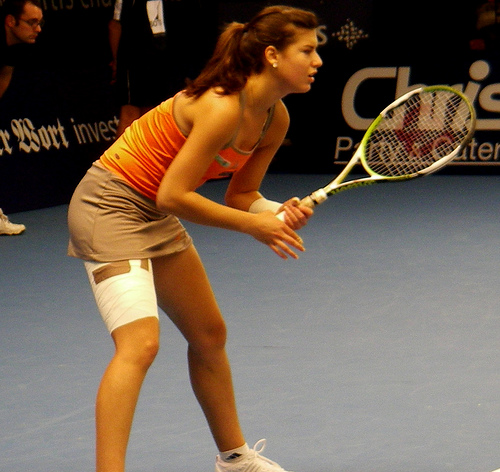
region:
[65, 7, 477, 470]
tennis player ready to receive serve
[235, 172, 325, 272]
a two hand grip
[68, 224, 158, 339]
a thigh wrapped because of injury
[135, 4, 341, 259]
woman with a nice tan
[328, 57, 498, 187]
sign written in English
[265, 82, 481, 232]
a white and green racquet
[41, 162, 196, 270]
a tan tennis skirt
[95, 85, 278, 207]
female player with orange top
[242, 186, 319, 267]
player flexing her right hand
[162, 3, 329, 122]
tennis player with a pony tail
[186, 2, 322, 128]
the girl has brown hair in a ponytail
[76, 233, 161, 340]
the girl has an ace bandage on her thigh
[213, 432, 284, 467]
she is wearing white tennis shoes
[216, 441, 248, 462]
she is wearing a white sock with a black logo on it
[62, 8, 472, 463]
the tennis player is waiting for a serve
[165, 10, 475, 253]
a tennis racket is in both hands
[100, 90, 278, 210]
an orange and gray shirt is on the girl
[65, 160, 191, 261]
the player is wearing a beige tennis skirt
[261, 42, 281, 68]
an earring is on her earlobe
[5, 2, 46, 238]
a lineman is wearing glasses on the side line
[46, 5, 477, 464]
a girl is playing tennis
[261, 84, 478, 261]
the girl has a tennis racket in both hands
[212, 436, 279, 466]
the player is wearing white tennis shoes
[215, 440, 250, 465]
the player is wearing socks with a logo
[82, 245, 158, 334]
an ace bandage is on the girl's thigh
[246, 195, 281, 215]
the girl is wearing a wrist band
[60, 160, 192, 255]
player is wearing a beige skirt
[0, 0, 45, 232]
a man is crouching behind her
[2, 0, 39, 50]
the man in a dark shirt is wearing glasses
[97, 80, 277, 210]
the tennis player is wearing a tank top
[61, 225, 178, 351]
a white leg bandage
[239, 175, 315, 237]
a taped up wrist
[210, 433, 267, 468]
a white adidas sock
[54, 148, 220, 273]
a short khaki skirt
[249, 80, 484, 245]
green and white tennis racket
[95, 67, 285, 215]
orange and tan athletic shirt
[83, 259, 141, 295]
brown tape on white bandage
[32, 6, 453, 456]
a woman playing tennis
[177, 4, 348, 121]
a woman with a brown ponytail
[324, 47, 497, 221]
a black and white advertisement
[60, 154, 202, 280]
grey tennis skirt on player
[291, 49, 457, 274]
lime green tennis racquet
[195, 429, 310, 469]
white socks and shoes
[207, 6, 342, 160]
hair in ponytail on player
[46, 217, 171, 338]
hamstring wrapped on player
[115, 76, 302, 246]
orange top on player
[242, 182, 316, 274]
hands gripped on racquet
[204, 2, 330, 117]
player concentrating on game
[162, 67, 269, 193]
top outlined in grey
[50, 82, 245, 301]
grey and coral tennis outfit